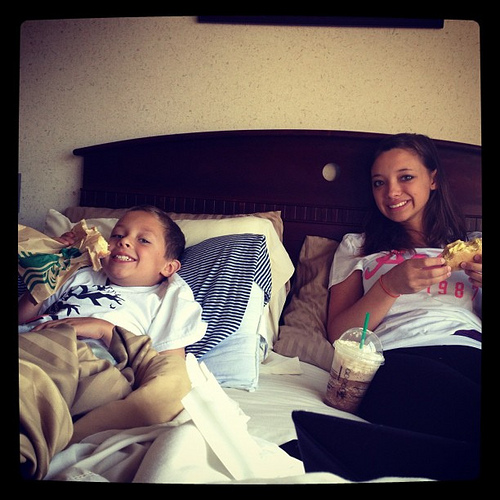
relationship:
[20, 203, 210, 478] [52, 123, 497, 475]
boy in bed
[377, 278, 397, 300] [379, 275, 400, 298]
hair tie on hair tie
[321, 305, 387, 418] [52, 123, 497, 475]
drink on bed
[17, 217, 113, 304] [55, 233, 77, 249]
starbucks bag in boy's hand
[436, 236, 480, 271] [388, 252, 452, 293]
sandwich in hand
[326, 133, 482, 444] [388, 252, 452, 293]
woman has hand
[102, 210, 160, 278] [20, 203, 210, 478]
face on boy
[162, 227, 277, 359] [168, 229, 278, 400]
pillow case on pillow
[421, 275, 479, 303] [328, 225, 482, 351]
1987 on woman's shirt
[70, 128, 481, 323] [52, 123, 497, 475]
headboard behind bed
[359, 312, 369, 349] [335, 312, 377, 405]
straw in drink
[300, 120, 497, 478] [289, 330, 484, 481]
woman wearing pants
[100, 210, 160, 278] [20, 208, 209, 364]
face on boy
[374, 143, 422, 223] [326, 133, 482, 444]
face on woman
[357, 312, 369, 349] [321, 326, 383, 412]
straw in drink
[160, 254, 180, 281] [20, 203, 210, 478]
ear on boy